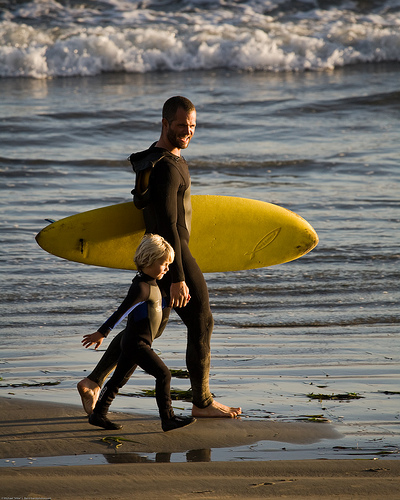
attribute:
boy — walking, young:
[80, 229, 198, 434]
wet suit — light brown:
[96, 276, 182, 417]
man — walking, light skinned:
[77, 95, 244, 419]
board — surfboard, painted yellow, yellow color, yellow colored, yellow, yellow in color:
[31, 189, 322, 282]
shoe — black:
[165, 411, 199, 431]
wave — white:
[0, 10, 400, 68]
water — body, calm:
[3, 4, 393, 285]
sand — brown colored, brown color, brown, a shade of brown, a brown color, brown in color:
[17, 324, 399, 494]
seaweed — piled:
[302, 386, 364, 402]